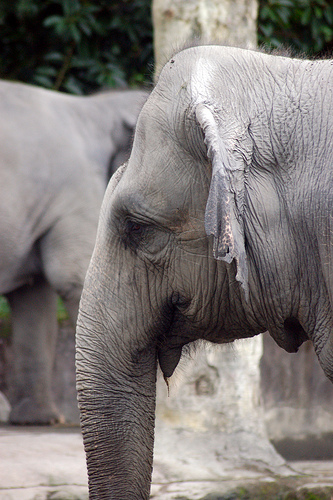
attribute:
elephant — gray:
[75, 44, 330, 500]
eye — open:
[129, 217, 140, 232]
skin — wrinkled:
[128, 46, 332, 380]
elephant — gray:
[1, 76, 151, 424]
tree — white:
[150, 1, 298, 476]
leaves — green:
[260, 3, 332, 55]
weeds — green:
[209, 484, 331, 500]